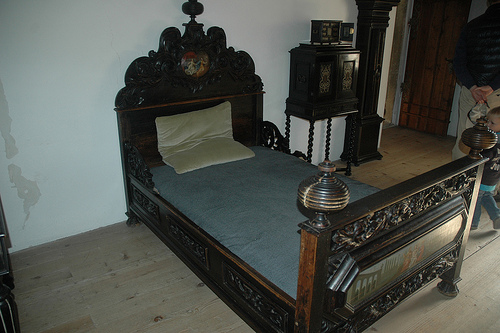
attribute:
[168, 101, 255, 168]
pillow — velvet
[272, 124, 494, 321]
footboard — small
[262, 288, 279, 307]
wood — dark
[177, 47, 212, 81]
portrait — framed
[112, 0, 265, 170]
headboard — carved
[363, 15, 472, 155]
door — wooden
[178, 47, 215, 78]
clock — grandfather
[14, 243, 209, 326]
floor — wood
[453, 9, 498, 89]
coat — black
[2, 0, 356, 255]
wall — white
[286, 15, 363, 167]
jewlery chest — dark, stained, wood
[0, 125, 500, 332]
floor — oak, wooden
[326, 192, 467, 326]
mural — framed